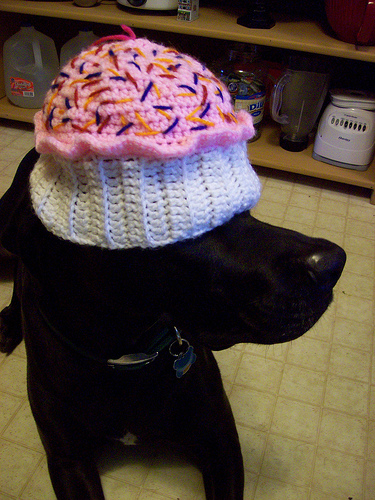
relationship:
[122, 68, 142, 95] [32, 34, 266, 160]
yarn on yarn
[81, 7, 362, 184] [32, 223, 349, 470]
shelves behind dog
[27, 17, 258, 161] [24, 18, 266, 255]
crocheted hat on hat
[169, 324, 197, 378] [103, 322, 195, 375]
tag on collar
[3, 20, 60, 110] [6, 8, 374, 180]
plastic jug on shelf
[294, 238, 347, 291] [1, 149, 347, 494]
nose on dog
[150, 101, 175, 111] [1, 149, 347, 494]
sprinkle on dog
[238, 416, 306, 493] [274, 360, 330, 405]
dog on tile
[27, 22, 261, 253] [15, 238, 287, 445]
beanie on dog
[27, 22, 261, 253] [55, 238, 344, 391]
beanie on dog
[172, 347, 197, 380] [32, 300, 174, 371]
tag on collar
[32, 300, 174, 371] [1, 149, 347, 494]
collar on dog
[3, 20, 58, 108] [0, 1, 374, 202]
plastic jug on shelf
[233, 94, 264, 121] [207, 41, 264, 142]
label on glass bottle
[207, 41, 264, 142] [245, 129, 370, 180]
glass bottle on wooden shelf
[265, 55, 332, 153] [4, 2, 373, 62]
pitcher on shelf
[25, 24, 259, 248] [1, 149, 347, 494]
beanie on dog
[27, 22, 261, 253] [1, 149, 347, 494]
beanie covering dogs eyes dog